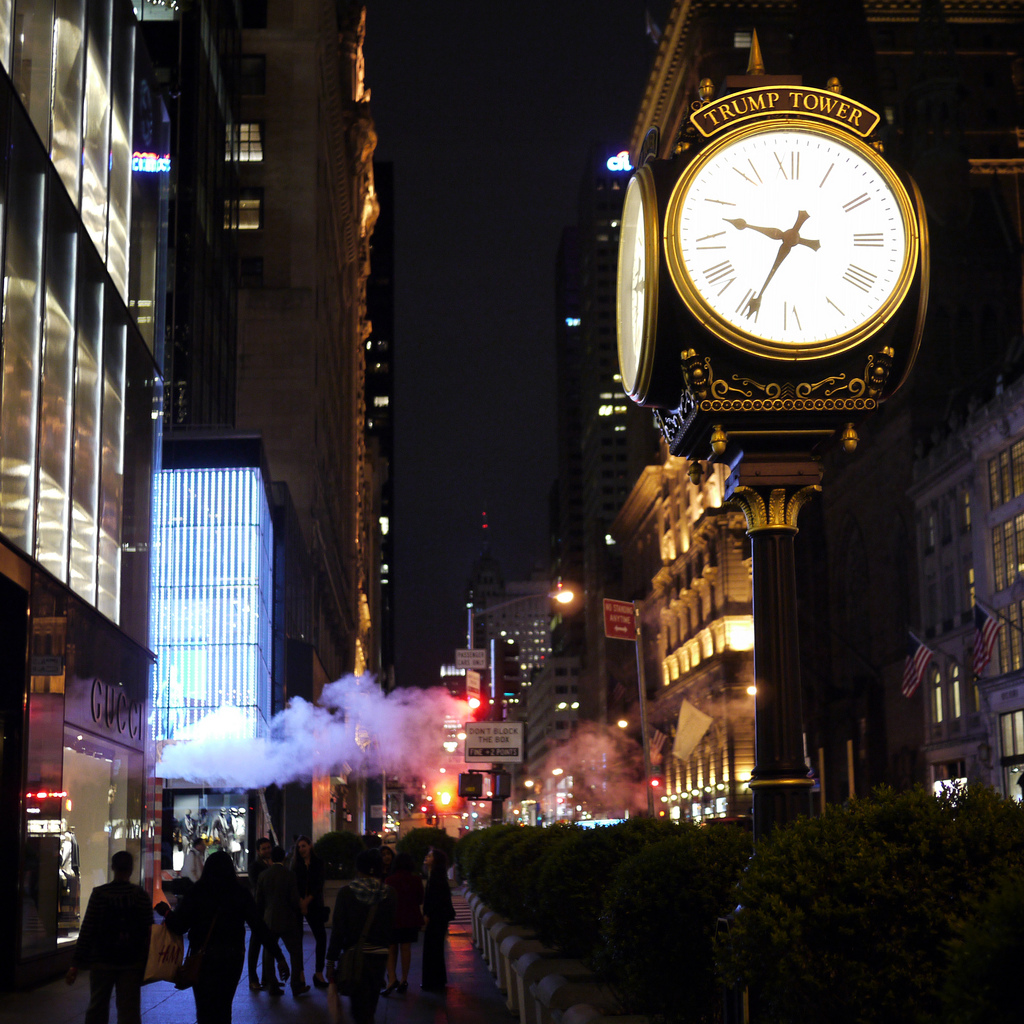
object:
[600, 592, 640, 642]
parking sign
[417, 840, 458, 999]
person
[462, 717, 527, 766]
sign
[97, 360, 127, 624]
window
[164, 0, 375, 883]
building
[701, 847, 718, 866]
leaves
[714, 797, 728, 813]
window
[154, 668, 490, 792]
steam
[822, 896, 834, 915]
leaves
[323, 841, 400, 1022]
woman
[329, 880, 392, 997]
backpack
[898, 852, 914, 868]
leaves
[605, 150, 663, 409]
clock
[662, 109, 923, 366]
clock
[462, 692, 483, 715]
light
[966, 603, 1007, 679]
american flag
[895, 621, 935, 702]
american flag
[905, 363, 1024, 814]
building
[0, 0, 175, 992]
building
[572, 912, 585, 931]
leaves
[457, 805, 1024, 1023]
bush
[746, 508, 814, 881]
pole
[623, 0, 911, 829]
building